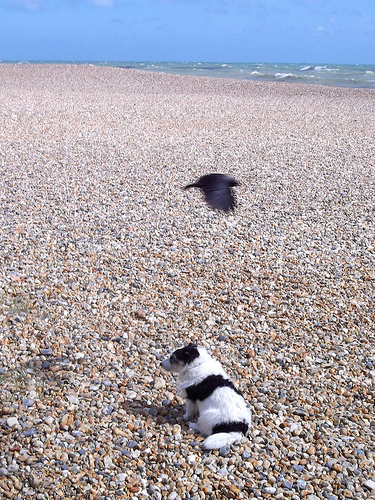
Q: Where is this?
A: This is at the beach.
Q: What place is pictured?
A: It is a beach.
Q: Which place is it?
A: It is a beach.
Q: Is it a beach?
A: Yes, it is a beach.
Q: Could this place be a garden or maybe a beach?
A: It is a beach.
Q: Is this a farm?
A: No, it is a beach.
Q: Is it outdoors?
A: Yes, it is outdoors.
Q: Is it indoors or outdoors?
A: It is outdoors.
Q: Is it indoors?
A: No, it is outdoors.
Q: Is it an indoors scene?
A: No, it is outdoors.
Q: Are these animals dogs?
A: No, they are dogs and birds.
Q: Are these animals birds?
A: No, they are dogs and birds.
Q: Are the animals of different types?
A: Yes, they are dogs and birds.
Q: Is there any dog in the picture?
A: Yes, there is a dog.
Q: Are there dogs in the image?
A: Yes, there is a dog.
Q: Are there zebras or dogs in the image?
A: Yes, there is a dog.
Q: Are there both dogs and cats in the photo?
A: No, there is a dog but no cats.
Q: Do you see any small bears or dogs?
A: Yes, there is a small dog.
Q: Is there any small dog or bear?
A: Yes, there is a small dog.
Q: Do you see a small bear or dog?
A: Yes, there is a small dog.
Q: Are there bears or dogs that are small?
A: Yes, the dog is small.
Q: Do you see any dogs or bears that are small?
A: Yes, the dog is small.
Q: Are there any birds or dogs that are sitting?
A: Yes, the dog is sitting.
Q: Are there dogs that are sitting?
A: Yes, there is a dog that is sitting.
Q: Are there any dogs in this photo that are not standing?
A: Yes, there is a dog that is sitting.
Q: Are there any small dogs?
A: Yes, there is a small dog.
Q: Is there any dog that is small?
A: Yes, there is a dog that is small.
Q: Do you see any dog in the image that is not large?
A: Yes, there is a small dog.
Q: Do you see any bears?
A: No, there are no bears.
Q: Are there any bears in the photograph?
A: No, there are no bears.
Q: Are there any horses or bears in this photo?
A: No, there are no bears or horses.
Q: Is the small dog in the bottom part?
A: Yes, the dog is in the bottom of the image.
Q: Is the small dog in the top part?
A: No, the dog is in the bottom of the image.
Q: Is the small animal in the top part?
A: No, the dog is in the bottom of the image.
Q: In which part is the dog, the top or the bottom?
A: The dog is in the bottom of the image.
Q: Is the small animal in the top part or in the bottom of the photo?
A: The dog is in the bottom of the image.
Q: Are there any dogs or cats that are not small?
A: No, there is a dog but it is small.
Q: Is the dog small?
A: Yes, the dog is small.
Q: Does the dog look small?
A: Yes, the dog is small.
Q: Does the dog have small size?
A: Yes, the dog is small.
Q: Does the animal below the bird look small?
A: Yes, the dog is small.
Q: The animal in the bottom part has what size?
A: The dog is small.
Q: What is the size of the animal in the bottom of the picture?
A: The dog is small.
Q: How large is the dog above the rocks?
A: The dog is small.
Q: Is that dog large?
A: No, the dog is small.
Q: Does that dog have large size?
A: No, the dog is small.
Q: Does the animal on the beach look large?
A: No, the dog is small.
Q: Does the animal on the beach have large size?
A: No, the dog is small.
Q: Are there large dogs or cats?
A: No, there is a dog but it is small.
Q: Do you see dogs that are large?
A: No, there is a dog but it is small.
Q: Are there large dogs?
A: No, there is a dog but it is small.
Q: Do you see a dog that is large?
A: No, there is a dog but it is small.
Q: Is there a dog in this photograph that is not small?
A: No, there is a dog but it is small.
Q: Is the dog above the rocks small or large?
A: The dog is small.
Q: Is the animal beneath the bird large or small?
A: The dog is small.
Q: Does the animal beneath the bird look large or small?
A: The dog is small.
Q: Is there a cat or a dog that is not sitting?
A: No, there is a dog but it is sitting.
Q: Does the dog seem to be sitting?
A: Yes, the dog is sitting.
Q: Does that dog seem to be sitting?
A: Yes, the dog is sitting.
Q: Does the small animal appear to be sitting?
A: Yes, the dog is sitting.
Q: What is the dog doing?
A: The dog is sitting.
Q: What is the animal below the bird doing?
A: The dog is sitting.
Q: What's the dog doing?
A: The dog is sitting.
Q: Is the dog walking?
A: No, the dog is sitting.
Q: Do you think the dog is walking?
A: No, the dog is sitting.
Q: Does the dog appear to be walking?
A: No, the dog is sitting.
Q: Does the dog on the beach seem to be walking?
A: No, the dog is sitting.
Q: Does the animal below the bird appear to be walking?
A: No, the dog is sitting.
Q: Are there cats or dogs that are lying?
A: No, there is a dog but it is sitting.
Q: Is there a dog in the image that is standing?
A: No, there is a dog but it is sitting.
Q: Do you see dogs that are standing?
A: No, there is a dog but it is sitting.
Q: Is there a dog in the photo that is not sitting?
A: No, there is a dog but it is sitting.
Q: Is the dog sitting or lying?
A: The dog is sitting.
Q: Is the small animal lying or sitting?
A: The dog is sitting.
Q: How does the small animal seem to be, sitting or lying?
A: The dog is sitting.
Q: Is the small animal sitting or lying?
A: The dog is sitting.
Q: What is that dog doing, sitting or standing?
A: The dog is sitting.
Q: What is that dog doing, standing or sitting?
A: The dog is sitting.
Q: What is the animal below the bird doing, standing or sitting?
A: The dog is sitting.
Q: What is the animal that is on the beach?
A: The animal is a dog.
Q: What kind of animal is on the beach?
A: The animal is a dog.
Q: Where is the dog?
A: The dog is on the beach.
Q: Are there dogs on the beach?
A: Yes, there is a dog on the beach.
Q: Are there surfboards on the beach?
A: No, there is a dog on the beach.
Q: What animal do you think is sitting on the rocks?
A: The dog is sitting on the rocks.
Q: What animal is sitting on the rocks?
A: The dog is sitting on the rocks.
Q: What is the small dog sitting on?
A: The dog is sitting on the rocks.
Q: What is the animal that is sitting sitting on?
A: The dog is sitting on the rocks.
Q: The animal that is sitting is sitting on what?
A: The dog is sitting on the rocks.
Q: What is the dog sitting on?
A: The dog is sitting on the rocks.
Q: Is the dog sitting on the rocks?
A: Yes, the dog is sitting on the rocks.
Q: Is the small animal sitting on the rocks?
A: Yes, the dog is sitting on the rocks.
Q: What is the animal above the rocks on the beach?
A: The animal is a dog.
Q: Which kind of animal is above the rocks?
A: The animal is a dog.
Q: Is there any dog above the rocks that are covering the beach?
A: Yes, there is a dog above the rocks.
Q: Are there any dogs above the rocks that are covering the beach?
A: Yes, there is a dog above the rocks.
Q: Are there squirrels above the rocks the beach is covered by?
A: No, there is a dog above the rocks.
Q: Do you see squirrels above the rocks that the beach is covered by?
A: No, there is a dog above the rocks.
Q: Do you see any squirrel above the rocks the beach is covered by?
A: No, there is a dog above the rocks.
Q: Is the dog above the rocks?
A: Yes, the dog is above the rocks.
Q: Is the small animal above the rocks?
A: Yes, the dog is above the rocks.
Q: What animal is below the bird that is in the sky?
A: The animal is a dog.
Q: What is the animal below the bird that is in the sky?
A: The animal is a dog.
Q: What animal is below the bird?
A: The animal is a dog.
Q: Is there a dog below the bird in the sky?
A: Yes, there is a dog below the bird.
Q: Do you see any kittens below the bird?
A: No, there is a dog below the bird.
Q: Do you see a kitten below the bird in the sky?
A: No, there is a dog below the bird.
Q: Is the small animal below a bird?
A: Yes, the dog is below a bird.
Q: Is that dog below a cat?
A: No, the dog is below a bird.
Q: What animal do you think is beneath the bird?
A: The dog is beneath the bird.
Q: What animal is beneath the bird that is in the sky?
A: The dog is beneath the bird.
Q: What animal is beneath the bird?
A: The dog is beneath the bird.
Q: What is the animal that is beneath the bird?
A: The animal is a dog.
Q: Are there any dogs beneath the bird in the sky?
A: Yes, there is a dog beneath the bird.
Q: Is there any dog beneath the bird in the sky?
A: Yes, there is a dog beneath the bird.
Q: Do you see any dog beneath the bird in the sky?
A: Yes, there is a dog beneath the bird.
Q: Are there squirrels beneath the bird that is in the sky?
A: No, there is a dog beneath the bird.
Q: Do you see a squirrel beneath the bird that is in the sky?
A: No, there is a dog beneath the bird.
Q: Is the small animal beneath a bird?
A: Yes, the dog is beneath a bird.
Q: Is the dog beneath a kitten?
A: No, the dog is beneath a bird.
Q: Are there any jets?
A: No, there are no jets.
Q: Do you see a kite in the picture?
A: No, there are no kites.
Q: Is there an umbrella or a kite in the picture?
A: No, there are no kites or umbrellas.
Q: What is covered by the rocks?
A: The beach is covered by the rocks.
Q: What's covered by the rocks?
A: The beach is covered by the rocks.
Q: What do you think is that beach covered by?
A: The beach is covered by the rocks.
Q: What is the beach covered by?
A: The beach is covered by the rocks.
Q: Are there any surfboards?
A: No, there are no surfboards.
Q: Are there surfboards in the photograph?
A: No, there are no surfboards.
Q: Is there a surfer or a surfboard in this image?
A: No, there are no surfboards or surfers.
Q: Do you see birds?
A: Yes, there is a bird.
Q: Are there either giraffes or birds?
A: Yes, there is a bird.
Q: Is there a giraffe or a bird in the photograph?
A: Yes, there is a bird.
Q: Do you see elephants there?
A: No, there are no elephants.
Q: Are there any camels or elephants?
A: No, there are no elephants or camels.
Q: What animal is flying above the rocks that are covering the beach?
A: The bird is flying above the rocks.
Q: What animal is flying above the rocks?
A: The bird is flying above the rocks.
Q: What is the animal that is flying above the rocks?
A: The animal is a bird.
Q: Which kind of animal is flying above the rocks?
A: The animal is a bird.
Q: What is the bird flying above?
A: The bird is flying above the rocks.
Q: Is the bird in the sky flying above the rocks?
A: Yes, the bird is flying above the rocks.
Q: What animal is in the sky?
A: The bird is in the sky.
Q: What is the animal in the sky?
A: The animal is a bird.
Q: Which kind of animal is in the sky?
A: The animal is a bird.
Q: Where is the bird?
A: The bird is in the sky.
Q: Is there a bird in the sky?
A: Yes, there is a bird in the sky.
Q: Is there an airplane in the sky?
A: No, there is a bird in the sky.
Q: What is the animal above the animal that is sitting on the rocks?
A: The animal is a bird.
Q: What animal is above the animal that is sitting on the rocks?
A: The animal is a bird.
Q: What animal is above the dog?
A: The animal is a bird.